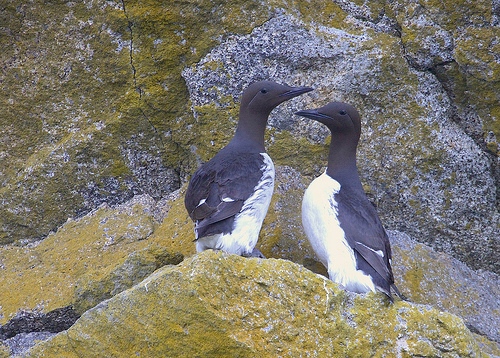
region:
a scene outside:
[35, 29, 453, 354]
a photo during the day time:
[15, 0, 445, 355]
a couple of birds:
[12, 11, 480, 355]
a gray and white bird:
[149, 48, 406, 299]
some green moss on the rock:
[7, 12, 188, 243]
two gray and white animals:
[29, 33, 444, 350]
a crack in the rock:
[363, 3, 498, 163]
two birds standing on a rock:
[150, 36, 427, 308]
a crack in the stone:
[112, 11, 159, 108]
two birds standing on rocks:
[190, 66, 395, 280]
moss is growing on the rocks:
[101, 53, 148, 123]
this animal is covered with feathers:
[186, 137, 260, 224]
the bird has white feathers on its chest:
[300, 179, 339, 264]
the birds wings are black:
[335, 180, 374, 258]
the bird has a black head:
[304, 101, 349, 146]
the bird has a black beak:
[302, 105, 321, 117]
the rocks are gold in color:
[130, 271, 239, 296]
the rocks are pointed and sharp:
[98, 281, 163, 296]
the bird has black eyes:
[257, 87, 269, 99]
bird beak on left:
[285, 76, 316, 97]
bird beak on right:
[295, 100, 310, 121]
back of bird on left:
[213, 160, 238, 196]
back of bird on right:
[354, 206, 371, 231]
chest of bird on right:
[313, 192, 322, 219]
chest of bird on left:
[264, 174, 271, 199]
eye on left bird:
[257, 79, 271, 96]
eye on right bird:
[338, 105, 349, 118]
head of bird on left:
[231, 58, 298, 123]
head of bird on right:
[318, 87, 365, 146]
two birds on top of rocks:
[156, 43, 408, 319]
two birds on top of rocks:
[200, 125, 383, 304]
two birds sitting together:
[185, 82, 392, 298]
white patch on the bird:
[301, 174, 371, 286]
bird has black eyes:
[260, 85, 266, 95]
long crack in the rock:
[118, 3, 164, 140]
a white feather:
[223, 195, 237, 203]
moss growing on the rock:
[130, 0, 182, 120]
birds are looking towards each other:
[234, 78, 367, 170]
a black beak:
[292, 107, 329, 119]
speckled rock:
[187, 22, 281, 112]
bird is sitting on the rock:
[186, 81, 313, 281]